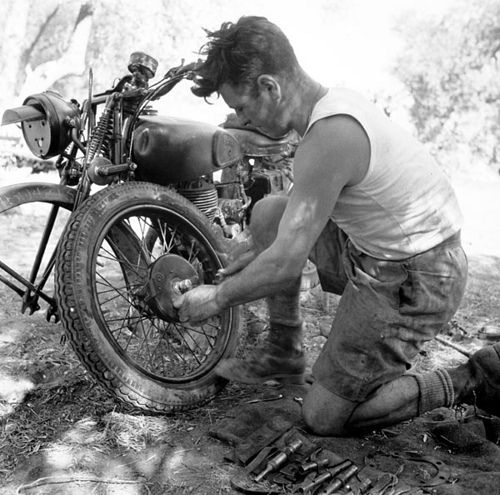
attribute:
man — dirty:
[174, 13, 498, 463]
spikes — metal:
[97, 218, 224, 376]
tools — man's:
[248, 434, 374, 494]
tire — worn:
[46, 175, 247, 419]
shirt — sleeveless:
[303, 86, 465, 241]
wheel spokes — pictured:
[91, 207, 230, 378]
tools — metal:
[213, 378, 343, 493]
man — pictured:
[185, 5, 499, 430]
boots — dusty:
[208, 325, 494, 411]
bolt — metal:
[178, 276, 195, 295]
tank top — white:
[308, 83, 464, 263]